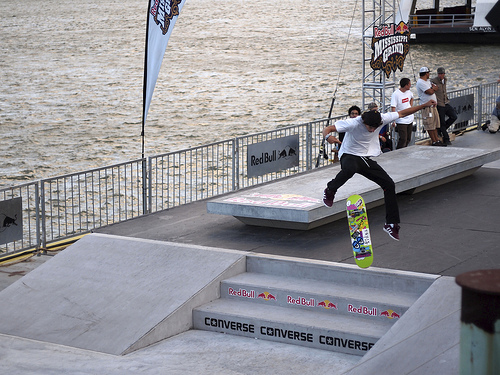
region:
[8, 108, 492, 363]
skateboard park on a pier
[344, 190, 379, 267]
green skateboard with stickers on the bottom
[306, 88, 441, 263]
man doing a skateboarding trick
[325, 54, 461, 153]
people leaning against fence watching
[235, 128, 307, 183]
white sign with black lettering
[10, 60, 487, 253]
silver metal fencing along pier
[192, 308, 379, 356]
converse logo on stairs of skateboard ramp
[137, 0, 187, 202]
flag attached to gates on pier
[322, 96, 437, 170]
man wearing a white t-shirt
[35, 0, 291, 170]
calm ocean water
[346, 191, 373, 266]
green skateboard with pictures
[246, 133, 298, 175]
white sign that says Red Bull in black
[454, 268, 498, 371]
top of green pole that is rusted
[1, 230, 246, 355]
concrete metal skate ramp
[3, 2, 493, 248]
body of water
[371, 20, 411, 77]
black sign that says Mississippi Grand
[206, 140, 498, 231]
large concrete platform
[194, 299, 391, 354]
concrete step that says Converse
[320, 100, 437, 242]
kid wearing a white tee shirt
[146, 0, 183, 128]
part of white flag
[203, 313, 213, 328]
The letter is black.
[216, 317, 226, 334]
The letter is black.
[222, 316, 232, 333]
The letter is black.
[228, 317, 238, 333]
The letter is black.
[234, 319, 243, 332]
The letter is black.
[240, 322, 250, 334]
The letter is black.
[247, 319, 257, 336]
The letter is black.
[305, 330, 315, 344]
The letter is black.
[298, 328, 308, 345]
The letter is black.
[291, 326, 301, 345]
The letter is black.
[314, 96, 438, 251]
A man flying through the air.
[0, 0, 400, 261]
A river filled with water.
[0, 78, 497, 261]
a long metal fence.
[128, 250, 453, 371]
a set of steps near a river.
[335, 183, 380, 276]
a skateboard falling down stairs.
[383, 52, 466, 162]
a group of friends.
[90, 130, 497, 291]
a paved area near a river.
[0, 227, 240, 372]
a cement skate ramp.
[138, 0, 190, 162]
a blue flag near a river.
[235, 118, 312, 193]
a banner on a fence.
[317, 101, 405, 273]
a boy doing a skateboard trick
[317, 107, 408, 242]
a boy wearing jeans and a white t-shirt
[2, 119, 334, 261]
metal fence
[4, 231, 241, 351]
a ramp used for skateboarding tricks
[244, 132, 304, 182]
an advertisement for Red Bull energy drink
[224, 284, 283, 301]
an advertisement for Red Bull energy drink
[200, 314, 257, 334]
an advertisement for Converse tennis shoes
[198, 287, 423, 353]
advertisements for event sponsors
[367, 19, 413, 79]
sign for the Mississippi Grand skateboarding tournament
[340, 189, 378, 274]
colorful lime-green skateboard